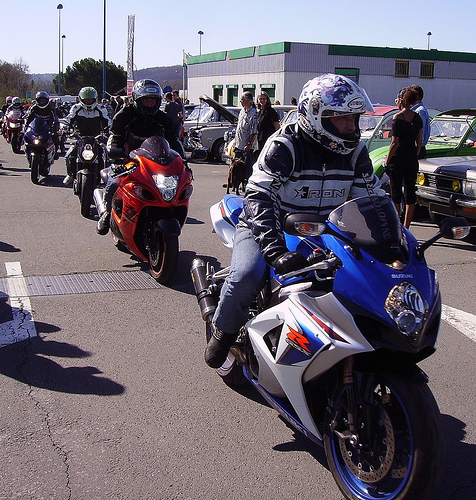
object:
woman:
[384, 89, 422, 231]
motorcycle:
[21, 126, 59, 184]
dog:
[222, 157, 251, 195]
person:
[96, 80, 195, 238]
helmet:
[130, 78, 163, 116]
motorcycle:
[93, 133, 209, 286]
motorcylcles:
[190, 191, 470, 499]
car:
[368, 110, 475, 199]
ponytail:
[406, 92, 419, 105]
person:
[203, 72, 405, 388]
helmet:
[296, 71, 377, 157]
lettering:
[285, 322, 312, 358]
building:
[185, 40, 475, 124]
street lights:
[194, 31, 206, 55]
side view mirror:
[285, 209, 323, 242]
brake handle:
[278, 265, 327, 288]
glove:
[275, 248, 307, 274]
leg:
[212, 207, 264, 335]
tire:
[320, 358, 446, 498]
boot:
[204, 331, 237, 367]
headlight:
[383, 281, 428, 341]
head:
[238, 89, 261, 107]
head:
[254, 90, 274, 109]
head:
[33, 91, 54, 108]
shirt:
[231, 111, 262, 153]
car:
[186, 94, 301, 164]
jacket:
[242, 121, 404, 261]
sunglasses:
[393, 98, 401, 105]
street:
[3, 212, 92, 464]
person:
[234, 90, 260, 166]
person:
[257, 93, 282, 149]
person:
[160, 93, 179, 121]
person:
[25, 91, 65, 162]